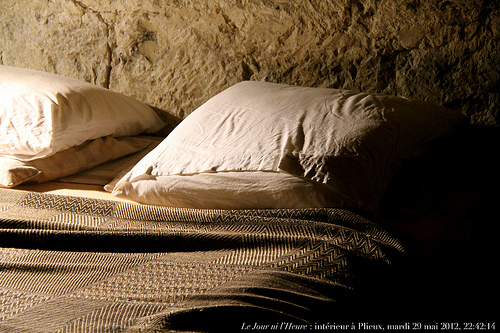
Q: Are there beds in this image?
A: Yes, there is a bed.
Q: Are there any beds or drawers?
A: Yes, there is a bed.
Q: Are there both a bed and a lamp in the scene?
A: No, there is a bed but no lamps.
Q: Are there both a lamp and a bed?
A: No, there is a bed but no lamps.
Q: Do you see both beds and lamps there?
A: No, there is a bed but no lamps.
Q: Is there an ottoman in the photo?
A: No, there are no ottomen.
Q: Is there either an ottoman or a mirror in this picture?
A: No, there are no ottomen or mirrors.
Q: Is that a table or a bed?
A: That is a bed.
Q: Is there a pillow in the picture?
A: Yes, there is a pillow.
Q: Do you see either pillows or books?
A: Yes, there is a pillow.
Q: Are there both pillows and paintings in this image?
A: No, there is a pillow but no paintings.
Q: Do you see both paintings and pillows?
A: No, there is a pillow but no paintings.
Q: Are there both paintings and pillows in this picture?
A: No, there is a pillow but no paintings.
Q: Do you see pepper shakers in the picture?
A: No, there are no pepper shakers.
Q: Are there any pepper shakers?
A: No, there are no pepper shakers.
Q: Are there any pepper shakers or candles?
A: No, there are no pepper shakers or candles.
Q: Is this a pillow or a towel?
A: This is a pillow.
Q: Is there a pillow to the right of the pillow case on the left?
A: Yes, there is a pillow to the right of the pillowcase.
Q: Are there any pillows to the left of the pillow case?
A: No, the pillow is to the right of the pillow case.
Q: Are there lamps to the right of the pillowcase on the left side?
A: No, there is a pillow to the right of the pillowcase.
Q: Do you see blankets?
A: Yes, there is a blanket.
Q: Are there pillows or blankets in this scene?
A: Yes, there is a blanket.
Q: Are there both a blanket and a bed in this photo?
A: Yes, there are both a blanket and a bed.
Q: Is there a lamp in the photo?
A: No, there are no lamps.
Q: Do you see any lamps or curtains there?
A: No, there are no lamps or curtains.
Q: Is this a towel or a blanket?
A: This is a blanket.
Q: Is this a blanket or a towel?
A: This is a blanket.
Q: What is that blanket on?
A: The blanket is on the bed.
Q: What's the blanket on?
A: The blanket is on the bed.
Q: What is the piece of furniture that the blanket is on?
A: The piece of furniture is a bed.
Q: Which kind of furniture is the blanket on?
A: The blanket is on the bed.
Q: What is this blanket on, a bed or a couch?
A: The blanket is on a bed.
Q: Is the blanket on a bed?
A: Yes, the blanket is on a bed.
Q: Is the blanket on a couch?
A: No, the blanket is on a bed.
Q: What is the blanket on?
A: The blanket is on the bed.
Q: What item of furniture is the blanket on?
A: The blanket is on the bed.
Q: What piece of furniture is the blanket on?
A: The blanket is on the bed.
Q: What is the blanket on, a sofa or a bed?
A: The blanket is on a bed.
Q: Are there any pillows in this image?
A: Yes, there is a pillow.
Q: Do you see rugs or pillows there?
A: Yes, there is a pillow.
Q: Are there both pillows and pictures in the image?
A: No, there is a pillow but no pictures.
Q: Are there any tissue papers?
A: No, there are no tissue papers.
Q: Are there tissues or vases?
A: No, there are no tissues or vases.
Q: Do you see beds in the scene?
A: Yes, there is a bed.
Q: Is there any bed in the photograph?
A: Yes, there is a bed.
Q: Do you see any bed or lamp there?
A: Yes, there is a bed.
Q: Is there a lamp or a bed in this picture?
A: Yes, there is a bed.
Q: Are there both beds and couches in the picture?
A: No, there is a bed but no couches.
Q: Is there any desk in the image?
A: No, there are no desks.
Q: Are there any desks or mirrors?
A: No, there are no desks or mirrors.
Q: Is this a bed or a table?
A: This is a bed.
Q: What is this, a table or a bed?
A: This is a bed.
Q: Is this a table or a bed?
A: This is a bed.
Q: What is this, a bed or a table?
A: This is a bed.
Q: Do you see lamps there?
A: No, there are no lamps.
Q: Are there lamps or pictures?
A: No, there are no lamps or pictures.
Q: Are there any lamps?
A: No, there are no lamps.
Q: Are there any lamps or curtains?
A: No, there are no lamps or curtains.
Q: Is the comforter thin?
A: Yes, the comforter is thin.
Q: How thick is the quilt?
A: The quilt is thin.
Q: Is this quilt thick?
A: No, the quilt is thin.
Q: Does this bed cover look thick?
A: No, the bed cover is thin.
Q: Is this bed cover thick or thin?
A: The bed cover is thin.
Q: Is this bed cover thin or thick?
A: The bed cover is thin.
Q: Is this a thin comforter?
A: Yes, this is a thin comforter.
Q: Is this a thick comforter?
A: No, this is a thin comforter.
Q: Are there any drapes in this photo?
A: No, there are no drapes.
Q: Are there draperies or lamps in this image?
A: No, there are no draperies or lamps.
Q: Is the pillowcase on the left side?
A: Yes, the pillowcase is on the left of the image.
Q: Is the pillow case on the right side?
A: No, the pillow case is on the left of the image.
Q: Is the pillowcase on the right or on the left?
A: The pillowcase is on the left of the image.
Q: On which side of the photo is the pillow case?
A: The pillow case is on the left of the image.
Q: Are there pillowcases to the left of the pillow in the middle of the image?
A: Yes, there is a pillowcase to the left of the pillow.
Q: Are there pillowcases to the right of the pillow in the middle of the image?
A: No, the pillowcase is to the left of the pillow.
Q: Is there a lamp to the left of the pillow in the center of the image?
A: No, there is a pillowcase to the left of the pillow.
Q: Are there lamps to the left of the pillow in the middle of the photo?
A: No, there is a pillowcase to the left of the pillow.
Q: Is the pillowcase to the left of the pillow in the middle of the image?
A: Yes, the pillowcase is to the left of the pillow.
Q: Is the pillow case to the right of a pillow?
A: No, the pillow case is to the left of a pillow.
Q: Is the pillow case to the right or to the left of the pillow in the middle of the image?
A: The pillow case is to the left of the pillow.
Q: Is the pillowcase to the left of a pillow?
A: Yes, the pillowcase is to the left of a pillow.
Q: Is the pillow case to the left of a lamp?
A: No, the pillow case is to the left of a pillow.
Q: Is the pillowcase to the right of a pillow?
A: No, the pillowcase is to the left of a pillow.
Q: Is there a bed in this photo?
A: Yes, there is a bed.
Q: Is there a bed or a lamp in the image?
A: Yes, there is a bed.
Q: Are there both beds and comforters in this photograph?
A: Yes, there are both a bed and a comforter.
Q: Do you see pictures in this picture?
A: No, there are no pictures.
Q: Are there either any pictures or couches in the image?
A: No, there are no pictures or couches.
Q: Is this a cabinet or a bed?
A: This is a bed.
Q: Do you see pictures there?
A: No, there are no pictures.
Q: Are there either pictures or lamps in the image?
A: No, there are no pictures or lamps.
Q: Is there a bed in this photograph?
A: Yes, there is a bed.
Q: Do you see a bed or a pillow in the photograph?
A: Yes, there is a bed.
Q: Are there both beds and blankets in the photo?
A: Yes, there are both a bed and a blanket.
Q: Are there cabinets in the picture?
A: No, there are no cabinets.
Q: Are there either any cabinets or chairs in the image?
A: No, there are no cabinets or chairs.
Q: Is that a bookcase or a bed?
A: That is a bed.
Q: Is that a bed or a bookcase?
A: That is a bed.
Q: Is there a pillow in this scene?
A: Yes, there are pillows.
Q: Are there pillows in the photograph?
A: Yes, there are pillows.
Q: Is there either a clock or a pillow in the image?
A: Yes, there are pillows.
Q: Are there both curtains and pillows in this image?
A: No, there are pillows but no curtains.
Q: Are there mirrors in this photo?
A: No, there are no mirrors.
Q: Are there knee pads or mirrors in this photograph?
A: No, there are no mirrors or knee pads.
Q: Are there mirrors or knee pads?
A: No, there are no mirrors or knee pads.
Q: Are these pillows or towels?
A: These are pillows.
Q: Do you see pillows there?
A: Yes, there are pillows.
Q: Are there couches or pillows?
A: Yes, there are pillows.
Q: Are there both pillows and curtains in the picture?
A: No, there are pillows but no curtains.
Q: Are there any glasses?
A: No, there are no glasses.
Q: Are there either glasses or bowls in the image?
A: No, there are no glasses or bowls.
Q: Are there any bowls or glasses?
A: No, there are no glasses or bowls.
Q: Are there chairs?
A: No, there are no chairs.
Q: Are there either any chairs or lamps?
A: No, there are no chairs or lamps.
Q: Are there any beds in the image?
A: Yes, there is a bed.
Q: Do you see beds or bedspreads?
A: Yes, there is a bed.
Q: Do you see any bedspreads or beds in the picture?
A: Yes, there is a bed.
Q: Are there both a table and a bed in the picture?
A: No, there is a bed but no tables.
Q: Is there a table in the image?
A: No, there are no tables.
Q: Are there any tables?
A: No, there are no tables.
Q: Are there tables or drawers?
A: No, there are no tables or drawers.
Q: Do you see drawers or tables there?
A: No, there are no tables or drawers.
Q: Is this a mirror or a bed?
A: This is a bed.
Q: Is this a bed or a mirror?
A: This is a bed.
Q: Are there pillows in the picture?
A: Yes, there is a pillow.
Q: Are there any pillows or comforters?
A: Yes, there is a pillow.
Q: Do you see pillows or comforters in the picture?
A: Yes, there is a pillow.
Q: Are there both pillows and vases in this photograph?
A: No, there is a pillow but no vases.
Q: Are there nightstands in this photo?
A: No, there are no nightstands.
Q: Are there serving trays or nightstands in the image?
A: No, there are no nightstands or serving trays.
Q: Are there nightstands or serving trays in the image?
A: No, there are no nightstands or serving trays.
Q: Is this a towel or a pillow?
A: This is a pillow.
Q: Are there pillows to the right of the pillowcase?
A: Yes, there is a pillow to the right of the pillowcase.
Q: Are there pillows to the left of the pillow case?
A: No, the pillow is to the right of the pillow case.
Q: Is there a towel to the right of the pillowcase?
A: No, there is a pillow to the right of the pillowcase.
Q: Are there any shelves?
A: No, there are no shelves.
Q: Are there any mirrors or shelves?
A: No, there are no shelves or mirrors.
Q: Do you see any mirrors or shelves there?
A: No, there are no shelves or mirrors.